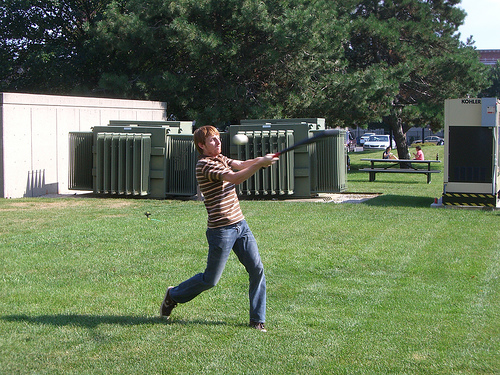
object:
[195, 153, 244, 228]
shirt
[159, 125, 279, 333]
man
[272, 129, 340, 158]
bat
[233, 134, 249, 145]
ball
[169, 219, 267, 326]
jeans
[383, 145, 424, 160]
kids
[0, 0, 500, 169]
tree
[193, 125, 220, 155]
hair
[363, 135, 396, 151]
car